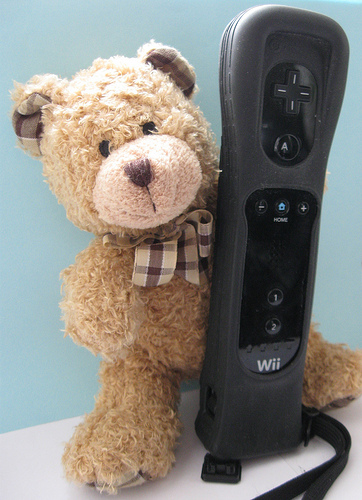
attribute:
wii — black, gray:
[193, 4, 351, 462]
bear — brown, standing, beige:
[9, 39, 361, 498]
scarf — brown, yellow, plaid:
[102, 208, 214, 286]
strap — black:
[250, 401, 351, 499]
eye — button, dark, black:
[99, 138, 112, 159]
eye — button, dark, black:
[141, 121, 160, 135]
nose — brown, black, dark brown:
[125, 158, 154, 187]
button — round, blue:
[265, 318, 283, 334]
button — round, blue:
[267, 288, 283, 306]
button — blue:
[254, 199, 269, 215]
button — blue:
[273, 198, 290, 214]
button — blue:
[298, 202, 309, 214]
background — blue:
[0, 0, 361, 436]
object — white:
[2, 388, 362, 500]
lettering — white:
[257, 356, 283, 373]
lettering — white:
[273, 215, 289, 225]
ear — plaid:
[138, 38, 198, 101]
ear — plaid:
[8, 71, 66, 161]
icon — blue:
[279, 203, 285, 212]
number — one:
[273, 294, 278, 304]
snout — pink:
[93, 134, 201, 228]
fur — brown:
[8, 37, 360, 494]